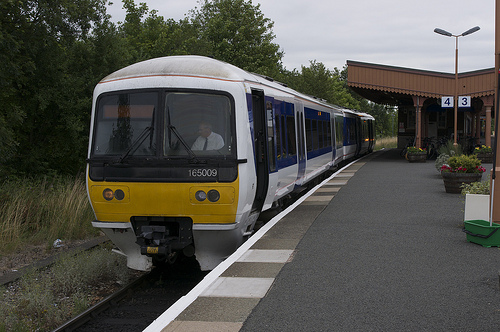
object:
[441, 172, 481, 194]
barrel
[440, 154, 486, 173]
flowers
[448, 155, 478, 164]
greenery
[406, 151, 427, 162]
barrel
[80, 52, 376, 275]
train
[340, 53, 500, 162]
building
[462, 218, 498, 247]
bucket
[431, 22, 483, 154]
light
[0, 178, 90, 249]
grass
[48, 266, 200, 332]
track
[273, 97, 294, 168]
window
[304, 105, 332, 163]
window trim